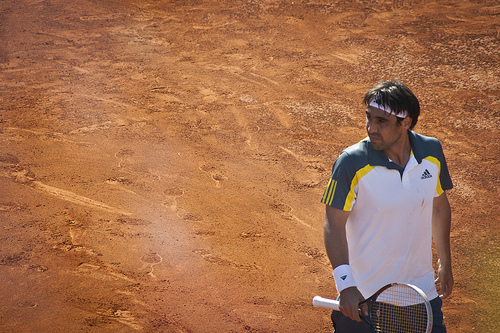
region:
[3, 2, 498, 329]
man on tennis court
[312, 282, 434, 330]
tennis racket in hand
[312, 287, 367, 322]
hand on white grip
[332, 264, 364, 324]
white band on wrist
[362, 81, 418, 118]
hair hanging over headband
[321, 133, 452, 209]
blue and yellow sleeves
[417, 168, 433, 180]
logo on shirt chest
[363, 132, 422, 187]
open collar of shirt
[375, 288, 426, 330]
yellow string in racket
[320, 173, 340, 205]
yellow stripes on sleeve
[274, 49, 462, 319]
man is playing tennis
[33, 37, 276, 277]
the dirt is reddish brown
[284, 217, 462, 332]
man is holding a racket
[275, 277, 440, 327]
the racket is white and black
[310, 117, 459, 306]
the shirt is mostly white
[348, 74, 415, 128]
man is wearing a headband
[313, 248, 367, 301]
man is wearing a wrist band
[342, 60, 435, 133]
man has dark hair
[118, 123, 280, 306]
foot prints in the dirt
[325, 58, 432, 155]
the man is looking to the left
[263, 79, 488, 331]
tennis player on clay court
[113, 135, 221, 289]
tennis court made of clay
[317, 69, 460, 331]
tennis player holding racket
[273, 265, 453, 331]
racket is black and white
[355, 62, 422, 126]
man wearing white head band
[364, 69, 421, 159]
hair hanging over head band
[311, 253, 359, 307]
man wearing white wrist band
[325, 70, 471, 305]
shirt is yellow, blue and white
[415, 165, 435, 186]
adidas logo on front of shirt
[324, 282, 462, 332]
shorts are blue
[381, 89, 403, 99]
black hair on mans head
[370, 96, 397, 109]
hair falling over white band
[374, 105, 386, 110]
white head band on mans head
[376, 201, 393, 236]
man wearing white shirt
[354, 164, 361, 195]
yellow stripe on mans shirt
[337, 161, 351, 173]
blue on mans shirt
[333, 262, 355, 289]
white wristband on wrist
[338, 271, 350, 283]
black symbol on wrist band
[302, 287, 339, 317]
bottom of tennis racket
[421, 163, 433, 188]
adidas sign on shirt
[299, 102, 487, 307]
man with a tennis racket in his right hand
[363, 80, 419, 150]
man has a white head band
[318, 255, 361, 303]
man has a white wrist ban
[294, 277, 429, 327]
tennis racket has a white handle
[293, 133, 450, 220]
man shirt is blue and yellow at his shoulder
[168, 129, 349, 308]
foot print on the brown ground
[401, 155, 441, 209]
blue insignia on shirt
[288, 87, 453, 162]
man looking to his right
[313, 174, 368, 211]
yellow strips on right sleeve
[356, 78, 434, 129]
man with dark hair